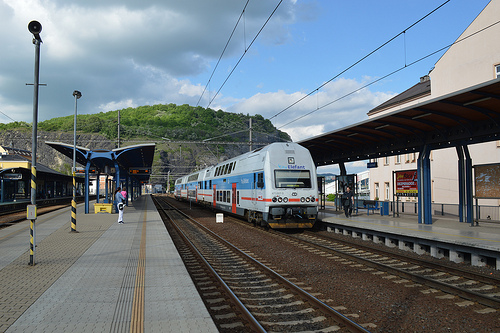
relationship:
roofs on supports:
[43, 133, 159, 177] [80, 148, 127, 194]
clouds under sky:
[253, 59, 375, 150] [253, 7, 467, 136]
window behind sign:
[367, 166, 409, 213] [391, 170, 420, 210]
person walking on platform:
[330, 168, 373, 228] [330, 196, 450, 235]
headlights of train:
[266, 192, 318, 207] [172, 141, 317, 226]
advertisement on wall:
[396, 169, 418, 197] [367, 140, 416, 215]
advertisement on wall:
[396, 169, 418, 197] [427, 145, 459, 217]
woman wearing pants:
[113, 184, 130, 225] [115, 202, 129, 222]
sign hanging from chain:
[389, 169, 426, 196] [367, 156, 379, 166]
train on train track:
[169, 139, 321, 231] [298, 229, 498, 298]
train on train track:
[169, 139, 321, 231] [158, 196, 364, 331]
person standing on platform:
[113, 184, 126, 229] [131, 192, 176, 325]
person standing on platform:
[341, 180, 359, 214] [131, 192, 176, 325]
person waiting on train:
[119, 185, 129, 205] [172, 141, 317, 226]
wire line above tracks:
[196, 9, 276, 99] [302, 222, 436, 269]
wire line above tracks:
[247, 32, 455, 149] [161, 188, 263, 319]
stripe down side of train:
[170, 169, 268, 193] [169, 139, 321, 231]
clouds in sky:
[52, 24, 84, 51] [306, 11, 360, 78]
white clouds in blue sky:
[183, 77, 398, 144] [173, 2, 493, 94]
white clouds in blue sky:
[94, 82, 240, 113] [173, 2, 493, 94]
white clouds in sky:
[66, 16, 168, 76] [5, 3, 467, 132]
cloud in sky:
[230, 93, 329, 122] [6, 0, 484, 141]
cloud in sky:
[309, 73, 396, 111] [6, 0, 484, 141]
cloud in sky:
[3, 2, 300, 103] [6, 0, 484, 141]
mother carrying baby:
[114, 182, 133, 222] [120, 183, 128, 201]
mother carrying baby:
[112, 185, 129, 225] [119, 189, 129, 201]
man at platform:
[330, 169, 359, 231] [321, 192, 499, 267]